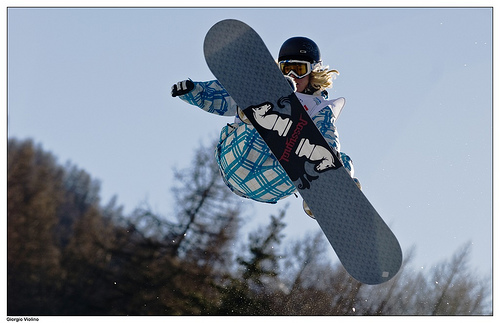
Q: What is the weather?
A: Sunny.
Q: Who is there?
A: A person.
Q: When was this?
A: Daytime.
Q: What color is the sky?
A: Blue.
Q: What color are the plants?
A: Green.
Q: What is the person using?
A: A snowboard.